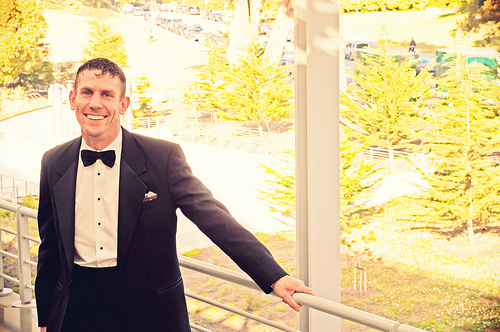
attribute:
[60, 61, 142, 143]
face — smiling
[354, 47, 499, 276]
trees — green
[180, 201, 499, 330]
handrail — gray, metal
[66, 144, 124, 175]
tie — black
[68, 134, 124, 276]
shirt — white, button up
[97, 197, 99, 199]
button — black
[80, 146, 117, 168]
tie — black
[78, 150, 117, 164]
bow tie — black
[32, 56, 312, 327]
man — smiling, brown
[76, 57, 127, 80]
hair — short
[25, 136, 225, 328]
men's suit — black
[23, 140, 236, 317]
shirt — white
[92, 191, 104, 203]
button — black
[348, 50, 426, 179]
tree — evergreen 